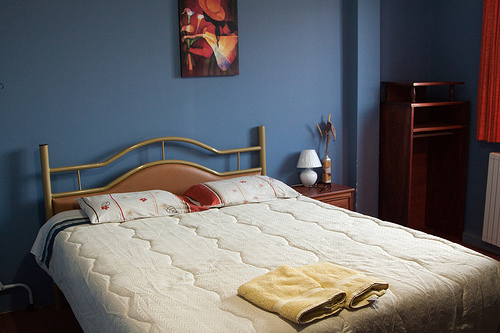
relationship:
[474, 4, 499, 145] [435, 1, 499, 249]
curtain hanging from wall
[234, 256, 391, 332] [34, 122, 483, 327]
towels on bed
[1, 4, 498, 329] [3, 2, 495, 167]
bedroom has walls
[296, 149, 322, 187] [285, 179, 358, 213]
lamp on side table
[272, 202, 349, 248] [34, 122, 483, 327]
bedspread on bed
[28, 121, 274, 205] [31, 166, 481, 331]
headboard between bed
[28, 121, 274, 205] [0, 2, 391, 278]
headboard between wall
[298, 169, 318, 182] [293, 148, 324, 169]
lamp with lamp shade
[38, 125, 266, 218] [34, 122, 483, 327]
headboard for bed